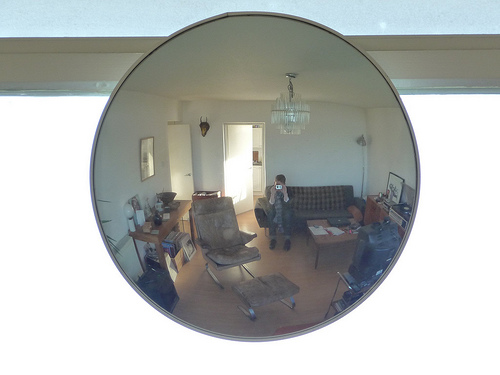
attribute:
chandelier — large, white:
[268, 92, 311, 143]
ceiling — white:
[242, 24, 314, 70]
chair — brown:
[190, 193, 266, 289]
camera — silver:
[275, 182, 287, 193]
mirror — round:
[80, 10, 429, 346]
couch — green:
[255, 182, 370, 232]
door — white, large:
[166, 120, 201, 204]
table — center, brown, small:
[130, 188, 195, 250]